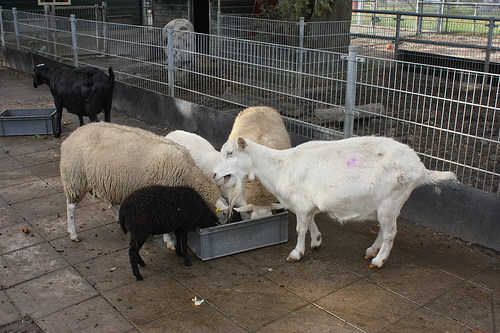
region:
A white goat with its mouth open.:
[212, 134, 459, 269]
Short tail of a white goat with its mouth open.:
[421, 162, 457, 187]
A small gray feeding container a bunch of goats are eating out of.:
[173, 205, 289, 260]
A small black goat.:
[115, 184, 221, 279]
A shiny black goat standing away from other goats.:
[31, 59, 115, 136]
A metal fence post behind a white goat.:
[345, 44, 357, 142]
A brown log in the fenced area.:
[315, 100, 385, 122]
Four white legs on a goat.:
[285, 206, 398, 269]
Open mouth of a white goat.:
[215, 170, 234, 189]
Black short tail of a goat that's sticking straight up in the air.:
[106, 64, 148, 136]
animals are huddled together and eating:
[50, 82, 455, 279]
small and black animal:
[104, 175, 236, 291]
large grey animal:
[28, 101, 267, 261]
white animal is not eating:
[200, 125, 482, 292]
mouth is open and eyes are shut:
[200, 141, 254, 185]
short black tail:
[108, 190, 139, 242]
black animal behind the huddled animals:
[22, 46, 136, 136]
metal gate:
[1, 0, 493, 190]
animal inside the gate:
[153, 8, 248, 120]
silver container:
[157, 175, 314, 263]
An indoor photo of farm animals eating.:
[1, 1, 498, 330]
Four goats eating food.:
[61, 106, 457, 265]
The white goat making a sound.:
[211, 135, 459, 265]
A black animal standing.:
[26, 55, 118, 132]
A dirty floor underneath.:
[1, 281, 495, 331]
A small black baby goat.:
[116, 186, 216, 284]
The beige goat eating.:
[55, 120, 222, 204]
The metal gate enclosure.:
[226, 46, 498, 99]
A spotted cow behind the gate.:
[156, 18, 194, 85]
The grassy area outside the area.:
[366, 7, 473, 34]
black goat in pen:
[32, 58, 122, 120]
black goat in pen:
[118, 177, 214, 284]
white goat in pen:
[215, 133, 454, 281]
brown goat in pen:
[37, 111, 228, 268]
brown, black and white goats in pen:
[71, 120, 456, 295]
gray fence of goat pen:
[160, 15, 488, 108]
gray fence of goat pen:
[388, 7, 498, 72]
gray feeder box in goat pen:
[223, 207, 287, 270]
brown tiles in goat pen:
[17, 206, 66, 321]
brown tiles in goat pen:
[95, 281, 493, 329]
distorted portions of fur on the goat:
[326, 132, 426, 202]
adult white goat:
[213, 117, 463, 265]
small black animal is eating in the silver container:
[88, 176, 249, 296]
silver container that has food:
[140, 181, 324, 261]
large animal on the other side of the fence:
[151, 3, 219, 93]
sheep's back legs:
[33, 134, 105, 267]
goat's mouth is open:
[211, 151, 251, 202]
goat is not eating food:
[209, 118, 477, 274]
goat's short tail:
[409, 147, 467, 195]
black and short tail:
[93, 57, 147, 121]